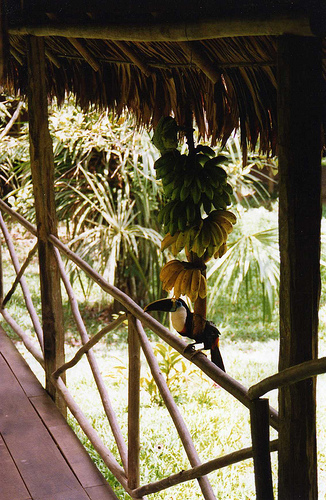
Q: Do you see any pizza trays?
A: No, there are no pizza trays.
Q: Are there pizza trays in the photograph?
A: No, there are no pizza trays.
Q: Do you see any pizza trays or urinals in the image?
A: No, there are no pizza trays or urinals.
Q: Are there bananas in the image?
A: Yes, there is a banana.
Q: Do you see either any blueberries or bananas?
A: Yes, there is a banana.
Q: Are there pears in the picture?
A: No, there are no pears.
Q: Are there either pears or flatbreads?
A: No, there are no pears or flatbreads.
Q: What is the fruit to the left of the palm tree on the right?
A: The fruit is a banana.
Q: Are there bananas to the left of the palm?
A: Yes, there is a banana to the left of the palm.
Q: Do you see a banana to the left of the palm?
A: Yes, there is a banana to the left of the palm.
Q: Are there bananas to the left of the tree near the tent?
A: Yes, there is a banana to the left of the palm.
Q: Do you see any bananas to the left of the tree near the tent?
A: Yes, there is a banana to the left of the palm.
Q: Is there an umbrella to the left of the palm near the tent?
A: No, there is a banana to the left of the palm.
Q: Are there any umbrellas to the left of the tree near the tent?
A: No, there is a banana to the left of the palm.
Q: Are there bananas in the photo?
A: Yes, there is a banana.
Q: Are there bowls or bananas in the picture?
A: Yes, there is a banana.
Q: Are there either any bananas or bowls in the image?
A: Yes, there is a banana.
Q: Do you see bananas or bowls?
A: Yes, there is a banana.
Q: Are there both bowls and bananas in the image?
A: No, there is a banana but no bowls.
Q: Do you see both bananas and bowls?
A: No, there is a banana but no bowls.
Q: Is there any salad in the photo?
A: No, there is no salad.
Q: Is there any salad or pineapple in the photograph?
A: No, there are no salad or pineapples.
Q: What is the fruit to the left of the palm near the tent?
A: The fruit is a banana.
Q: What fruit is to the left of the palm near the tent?
A: The fruit is a banana.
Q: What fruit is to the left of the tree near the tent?
A: The fruit is a banana.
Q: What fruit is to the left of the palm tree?
A: The fruit is a banana.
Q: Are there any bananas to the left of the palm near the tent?
A: Yes, there is a banana to the left of the palm tree.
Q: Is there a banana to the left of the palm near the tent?
A: Yes, there is a banana to the left of the palm tree.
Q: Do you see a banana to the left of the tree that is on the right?
A: Yes, there is a banana to the left of the palm tree.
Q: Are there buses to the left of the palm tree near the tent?
A: No, there is a banana to the left of the palm tree.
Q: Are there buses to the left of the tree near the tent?
A: No, there is a banana to the left of the palm tree.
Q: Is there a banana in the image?
A: Yes, there is a banana.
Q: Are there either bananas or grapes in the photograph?
A: Yes, there is a banana.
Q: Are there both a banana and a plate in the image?
A: No, there is a banana but no plates.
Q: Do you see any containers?
A: No, there are no containers.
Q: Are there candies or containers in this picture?
A: No, there are no containers or candies.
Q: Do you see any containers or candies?
A: No, there are no containers or candies.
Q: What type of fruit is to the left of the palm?
A: The fruit is a banana.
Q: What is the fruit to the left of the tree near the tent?
A: The fruit is a banana.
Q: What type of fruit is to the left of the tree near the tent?
A: The fruit is a banana.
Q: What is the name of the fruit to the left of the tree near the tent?
A: The fruit is a banana.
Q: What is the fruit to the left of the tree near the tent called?
A: The fruit is a banana.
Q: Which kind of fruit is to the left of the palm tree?
A: The fruit is a banana.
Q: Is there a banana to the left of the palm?
A: Yes, there is a banana to the left of the palm.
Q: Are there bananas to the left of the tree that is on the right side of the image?
A: Yes, there is a banana to the left of the palm.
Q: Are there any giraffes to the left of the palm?
A: No, there is a banana to the left of the palm.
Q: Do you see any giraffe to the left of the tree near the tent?
A: No, there is a banana to the left of the palm.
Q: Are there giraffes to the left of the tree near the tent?
A: No, there is a banana to the left of the palm.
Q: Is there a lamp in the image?
A: No, there are no lamps.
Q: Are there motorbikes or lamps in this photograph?
A: No, there are no lamps or motorbikes.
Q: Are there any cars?
A: No, there are no cars.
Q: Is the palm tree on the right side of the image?
A: Yes, the palm tree is on the right of the image.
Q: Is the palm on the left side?
A: No, the palm is on the right of the image.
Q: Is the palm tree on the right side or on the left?
A: The palm tree is on the right of the image.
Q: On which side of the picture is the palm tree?
A: The palm tree is on the right of the image.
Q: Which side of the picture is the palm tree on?
A: The palm tree is on the right of the image.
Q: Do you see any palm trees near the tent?
A: Yes, there is a palm tree near the tent.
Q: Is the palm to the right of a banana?
A: Yes, the palm is to the right of a banana.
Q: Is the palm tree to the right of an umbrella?
A: No, the palm tree is to the right of a banana.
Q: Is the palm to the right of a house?
A: No, the palm is to the right of a banana.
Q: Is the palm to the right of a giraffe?
A: No, the palm is to the right of the banana.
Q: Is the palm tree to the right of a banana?
A: Yes, the palm tree is to the right of a banana.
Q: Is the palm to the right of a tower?
A: No, the palm is to the right of a banana.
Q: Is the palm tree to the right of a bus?
A: No, the palm tree is to the right of a banana.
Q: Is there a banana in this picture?
A: Yes, there is a banana.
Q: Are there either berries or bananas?
A: Yes, there is a banana.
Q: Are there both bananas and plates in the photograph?
A: No, there is a banana but no plates.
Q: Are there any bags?
A: No, there are no bags.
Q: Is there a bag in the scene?
A: No, there are no bags.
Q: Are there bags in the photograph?
A: No, there are no bags.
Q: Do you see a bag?
A: No, there are no bags.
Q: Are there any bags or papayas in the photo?
A: No, there are no bags or papayas.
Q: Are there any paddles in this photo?
A: No, there are no paddles.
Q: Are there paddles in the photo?
A: No, there are no paddles.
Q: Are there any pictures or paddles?
A: No, there are no paddles or pictures.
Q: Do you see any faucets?
A: No, there are no faucets.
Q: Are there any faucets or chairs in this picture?
A: No, there are no faucets or chairs.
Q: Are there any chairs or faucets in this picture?
A: No, there are no faucets or chairs.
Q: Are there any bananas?
A: Yes, there is a banana.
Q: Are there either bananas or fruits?
A: Yes, there is a banana.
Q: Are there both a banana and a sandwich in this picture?
A: No, there is a banana but no sandwiches.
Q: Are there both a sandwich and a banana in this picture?
A: No, there is a banana but no sandwiches.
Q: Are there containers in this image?
A: No, there are no containers.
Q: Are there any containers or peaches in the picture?
A: No, there are no containers or peaches.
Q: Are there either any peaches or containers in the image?
A: No, there are no containers or peaches.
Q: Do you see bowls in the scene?
A: No, there are no bowls.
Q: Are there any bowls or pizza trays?
A: No, there are no bowls or pizza trays.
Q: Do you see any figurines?
A: No, there are no figurines.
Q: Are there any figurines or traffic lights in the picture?
A: No, there are no figurines or traffic lights.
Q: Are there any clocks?
A: No, there are no clocks.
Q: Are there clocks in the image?
A: No, there are no clocks.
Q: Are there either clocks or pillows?
A: No, there are no clocks or pillows.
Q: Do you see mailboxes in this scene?
A: No, there are no mailboxes.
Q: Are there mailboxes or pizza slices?
A: No, there are no mailboxes or pizza slices.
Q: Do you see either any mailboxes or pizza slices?
A: No, there are no mailboxes or pizza slices.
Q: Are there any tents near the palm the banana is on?
A: Yes, there is a tent near the palm.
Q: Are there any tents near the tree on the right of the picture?
A: Yes, there is a tent near the palm.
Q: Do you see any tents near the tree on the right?
A: Yes, there is a tent near the palm.